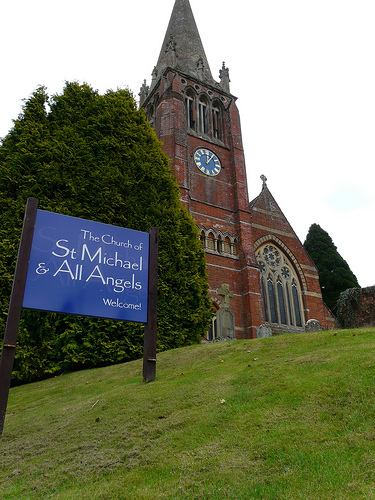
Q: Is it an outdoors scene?
A: Yes, it is outdoors.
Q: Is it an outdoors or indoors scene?
A: It is outdoors.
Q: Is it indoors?
A: No, it is outdoors.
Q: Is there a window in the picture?
A: Yes, there is a window.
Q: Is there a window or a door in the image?
A: Yes, there is a window.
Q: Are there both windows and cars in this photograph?
A: No, there is a window but no cars.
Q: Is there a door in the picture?
A: No, there are no doors.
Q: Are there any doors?
A: No, there are no doors.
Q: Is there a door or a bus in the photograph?
A: No, there are no doors or buses.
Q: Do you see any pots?
A: No, there are no pots.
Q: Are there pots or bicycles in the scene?
A: No, there are no pots or bicycles.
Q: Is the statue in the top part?
A: Yes, the statue is in the top of the image.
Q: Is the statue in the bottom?
A: No, the statue is in the top of the image.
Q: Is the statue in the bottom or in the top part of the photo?
A: The statue is in the top of the image.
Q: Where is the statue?
A: The statue is at the roof.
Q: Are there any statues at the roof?
A: Yes, there is a statue at the roof.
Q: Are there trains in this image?
A: No, there are no trains.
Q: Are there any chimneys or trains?
A: No, there are no trains or chimneys.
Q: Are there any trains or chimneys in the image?
A: No, there are no trains or chimneys.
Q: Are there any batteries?
A: No, there are no batteries.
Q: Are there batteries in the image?
A: No, there are no batteries.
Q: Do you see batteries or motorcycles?
A: No, there are no batteries or motorcycles.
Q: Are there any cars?
A: No, there are no cars.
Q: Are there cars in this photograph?
A: No, there are no cars.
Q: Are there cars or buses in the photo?
A: No, there are no cars or buses.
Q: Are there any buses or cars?
A: No, there are no cars or buses.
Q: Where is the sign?
A: The sign is on the grass.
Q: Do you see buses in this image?
A: No, there are no buses.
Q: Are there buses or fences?
A: No, there are no buses or fences.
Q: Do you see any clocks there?
A: Yes, there is a clock.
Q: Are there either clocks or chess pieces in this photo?
A: Yes, there is a clock.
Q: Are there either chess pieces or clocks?
A: Yes, there is a clock.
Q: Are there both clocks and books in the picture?
A: No, there is a clock but no books.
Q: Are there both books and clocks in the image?
A: No, there is a clock but no books.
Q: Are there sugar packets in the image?
A: No, there are no sugar packets.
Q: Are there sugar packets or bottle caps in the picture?
A: No, there are no sugar packets or bottle caps.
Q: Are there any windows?
A: Yes, there is a window.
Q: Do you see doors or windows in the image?
A: Yes, there is a window.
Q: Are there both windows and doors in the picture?
A: No, there is a window but no doors.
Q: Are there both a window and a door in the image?
A: No, there is a window but no doors.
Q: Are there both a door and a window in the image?
A: No, there is a window but no doors.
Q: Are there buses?
A: No, there are no buses.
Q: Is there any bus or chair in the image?
A: No, there are no buses or chairs.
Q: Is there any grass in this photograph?
A: Yes, there is grass.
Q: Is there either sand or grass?
A: Yes, there is grass.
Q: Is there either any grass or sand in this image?
A: Yes, there is grass.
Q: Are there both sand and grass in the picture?
A: No, there is grass but no sand.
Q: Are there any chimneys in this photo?
A: No, there are no chimneys.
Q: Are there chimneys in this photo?
A: No, there are no chimneys.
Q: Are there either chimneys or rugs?
A: No, there are no chimneys or rugs.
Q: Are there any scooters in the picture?
A: No, there are no scooters.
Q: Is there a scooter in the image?
A: No, there are no scooters.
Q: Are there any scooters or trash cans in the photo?
A: No, there are no scooters or trash cans.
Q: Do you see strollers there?
A: No, there are no strollers.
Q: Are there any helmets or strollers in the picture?
A: No, there are no strollers or helmets.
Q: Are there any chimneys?
A: No, there are no chimneys.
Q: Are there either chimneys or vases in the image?
A: No, there are no chimneys or vases.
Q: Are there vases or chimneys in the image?
A: No, there are no chimneys or vases.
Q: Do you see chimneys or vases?
A: No, there are no chimneys or vases.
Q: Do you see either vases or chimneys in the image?
A: No, there are no chimneys or vases.